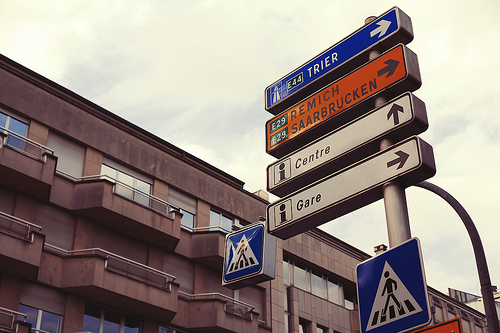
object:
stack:
[260, 5, 438, 242]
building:
[1, 54, 495, 328]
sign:
[222, 222, 265, 287]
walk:
[236, 239, 248, 264]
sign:
[354, 237, 431, 332]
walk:
[380, 270, 402, 317]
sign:
[263, 41, 408, 154]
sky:
[1, 1, 500, 316]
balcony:
[2, 126, 57, 202]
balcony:
[71, 173, 185, 252]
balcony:
[0, 210, 50, 284]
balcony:
[63, 247, 182, 325]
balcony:
[190, 291, 262, 333]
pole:
[380, 186, 413, 248]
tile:
[304, 291, 311, 315]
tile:
[315, 238, 322, 252]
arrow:
[369, 19, 392, 38]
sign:
[263, 5, 402, 111]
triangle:
[364, 259, 423, 332]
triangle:
[224, 233, 260, 275]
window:
[5, 114, 31, 155]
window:
[114, 169, 136, 202]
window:
[326, 274, 344, 308]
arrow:
[386, 103, 404, 125]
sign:
[266, 90, 415, 193]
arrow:
[386, 150, 410, 170]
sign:
[266, 135, 423, 234]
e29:
[271, 117, 285, 130]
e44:
[287, 74, 301, 90]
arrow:
[376, 59, 401, 79]